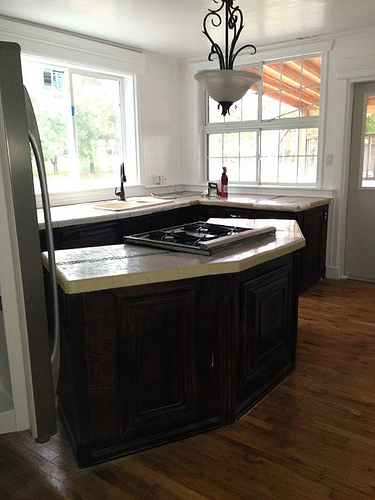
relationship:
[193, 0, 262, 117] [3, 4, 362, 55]
fixture hanging from ceiling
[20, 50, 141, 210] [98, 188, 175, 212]
window behind sink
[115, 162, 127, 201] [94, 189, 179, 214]
faucet on sink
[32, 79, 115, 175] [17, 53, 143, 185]
tree outside window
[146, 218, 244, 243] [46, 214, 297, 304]
range on counter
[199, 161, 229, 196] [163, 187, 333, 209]
items on counter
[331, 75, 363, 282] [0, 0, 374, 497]
door in kitchen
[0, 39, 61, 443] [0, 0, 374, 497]
refrigerator in kitchen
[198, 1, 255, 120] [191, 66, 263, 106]
fixture with glass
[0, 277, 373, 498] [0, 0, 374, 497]
floor in kitchen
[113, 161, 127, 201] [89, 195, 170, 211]
faucet by sink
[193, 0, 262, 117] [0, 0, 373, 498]
fixture hanging from building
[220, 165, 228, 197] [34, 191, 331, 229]
bottle sitting on counter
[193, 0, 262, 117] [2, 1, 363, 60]
fixture hanging from ceiling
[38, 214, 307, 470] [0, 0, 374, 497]
island sitting in middle of kitchen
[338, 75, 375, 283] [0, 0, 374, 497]
door leading to kitchen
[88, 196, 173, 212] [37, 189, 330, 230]
sink built into countertop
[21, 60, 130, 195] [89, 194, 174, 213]
window built above sink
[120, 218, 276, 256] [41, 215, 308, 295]
stove top built into counter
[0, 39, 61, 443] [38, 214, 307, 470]
refrigerator opened next to island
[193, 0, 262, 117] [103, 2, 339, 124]
fixture hanging on ceiling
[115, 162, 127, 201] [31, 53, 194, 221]
faucet in front of window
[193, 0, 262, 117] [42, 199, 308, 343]
fixture above counter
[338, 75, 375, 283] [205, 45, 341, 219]
door next to a window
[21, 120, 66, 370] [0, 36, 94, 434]
handle on refrigerator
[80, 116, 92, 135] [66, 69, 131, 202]
leaves on tree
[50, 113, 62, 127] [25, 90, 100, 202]
leaves on tree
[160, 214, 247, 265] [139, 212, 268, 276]
burner on stove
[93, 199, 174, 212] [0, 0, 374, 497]
sink in kitchen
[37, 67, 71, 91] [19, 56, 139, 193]
stickers on a window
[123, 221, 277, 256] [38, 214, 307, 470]
stove top on an island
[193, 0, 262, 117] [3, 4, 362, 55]
fixture hanging from a ceiling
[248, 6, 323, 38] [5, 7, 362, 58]
light reflecting on ceiling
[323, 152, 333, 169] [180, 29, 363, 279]
switch on wall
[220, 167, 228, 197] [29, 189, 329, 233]
bottle on counter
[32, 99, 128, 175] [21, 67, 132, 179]
trees outside window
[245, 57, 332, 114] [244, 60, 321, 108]
beams of a roof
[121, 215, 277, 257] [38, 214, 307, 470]
grill on an island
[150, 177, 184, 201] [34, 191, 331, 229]
cords on counter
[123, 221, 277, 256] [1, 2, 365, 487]
stove top on counter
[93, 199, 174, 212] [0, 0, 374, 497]
sink sitting in kitchen